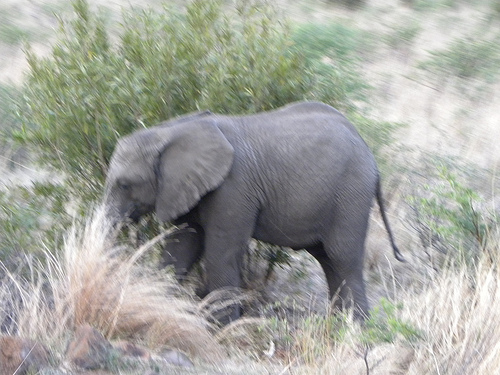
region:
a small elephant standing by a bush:
[97, 89, 394, 351]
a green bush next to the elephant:
[12, 9, 312, 145]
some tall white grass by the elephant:
[12, 209, 193, 373]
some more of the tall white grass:
[400, 260, 499, 372]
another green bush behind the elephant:
[394, 161, 484, 261]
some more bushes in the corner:
[375, 13, 493, 118]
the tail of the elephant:
[373, 172, 413, 276]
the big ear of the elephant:
[155, 126, 233, 241]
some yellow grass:
[393, 88, 491, 157]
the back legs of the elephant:
[309, 245, 376, 313]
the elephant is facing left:
[92, 96, 399, 334]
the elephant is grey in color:
[90, 93, 404, 331]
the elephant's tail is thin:
[372, 176, 408, 270]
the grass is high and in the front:
[2, 205, 498, 373]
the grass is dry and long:
[1, 213, 498, 374]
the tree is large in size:
[17, 0, 372, 293]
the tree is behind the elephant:
[16, 6, 356, 291]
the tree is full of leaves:
[22, 3, 341, 246]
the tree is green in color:
[20, 8, 340, 280]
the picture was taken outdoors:
[1, 0, 496, 373]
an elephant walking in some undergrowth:
[29, 67, 464, 373]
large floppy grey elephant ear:
[149, 115, 246, 230]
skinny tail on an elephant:
[368, 165, 413, 268]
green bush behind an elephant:
[13, 0, 375, 216]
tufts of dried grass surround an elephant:
[0, 202, 493, 373]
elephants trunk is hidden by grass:
[78, 175, 148, 280]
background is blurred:
[8, 5, 498, 172]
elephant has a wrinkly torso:
[219, 102, 289, 241]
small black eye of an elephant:
[112, 175, 132, 195]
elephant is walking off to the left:
[75, 88, 425, 348]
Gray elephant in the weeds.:
[104, 100, 405, 323]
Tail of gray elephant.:
[374, 172, 408, 263]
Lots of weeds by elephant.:
[30, 207, 223, 364]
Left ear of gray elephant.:
[155, 119, 230, 226]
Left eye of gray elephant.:
[115, 174, 133, 192]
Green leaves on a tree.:
[56, 47, 83, 85]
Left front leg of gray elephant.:
[200, 209, 255, 325]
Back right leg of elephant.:
[325, 227, 367, 337]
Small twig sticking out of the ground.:
[353, 344, 370, 374]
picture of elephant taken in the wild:
[76, 56, 418, 338]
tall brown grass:
[50, 200, 165, 342]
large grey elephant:
[103, 83, 410, 333]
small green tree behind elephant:
[40, 13, 281, 160]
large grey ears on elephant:
[146, 113, 242, 237]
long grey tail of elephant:
[366, 156, 417, 274]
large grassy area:
[79, 253, 482, 359]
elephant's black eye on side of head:
[109, 161, 145, 204]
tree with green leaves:
[62, 16, 245, 130]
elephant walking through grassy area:
[60, 83, 450, 342]